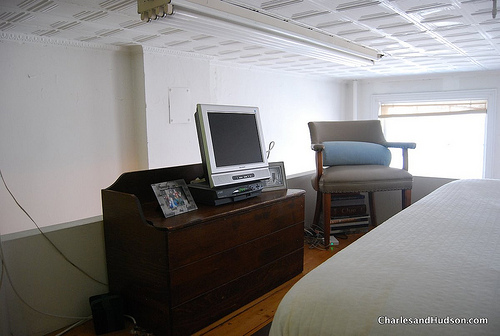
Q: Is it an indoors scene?
A: Yes, it is indoors.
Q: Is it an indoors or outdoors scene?
A: It is indoors.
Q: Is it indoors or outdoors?
A: It is indoors.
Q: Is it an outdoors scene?
A: No, it is indoors.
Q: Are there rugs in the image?
A: No, there are no rugs.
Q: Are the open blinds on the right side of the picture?
A: Yes, the blinds are on the right of the image.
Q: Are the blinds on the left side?
A: No, the blinds are on the right of the image.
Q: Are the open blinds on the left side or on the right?
A: The blinds are on the right of the image.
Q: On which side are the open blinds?
A: The blinds are on the right of the image.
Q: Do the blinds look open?
A: Yes, the blinds are open.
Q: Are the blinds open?
A: Yes, the blinds are open.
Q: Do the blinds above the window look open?
A: Yes, the blinds are open.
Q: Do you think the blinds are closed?
A: No, the blinds are open.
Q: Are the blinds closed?
A: No, the blinds are open.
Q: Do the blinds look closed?
A: No, the blinds are open.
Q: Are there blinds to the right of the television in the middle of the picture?
A: Yes, there are blinds to the right of the television.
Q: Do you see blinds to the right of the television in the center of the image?
A: Yes, there are blinds to the right of the television.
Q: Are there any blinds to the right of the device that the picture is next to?
A: Yes, there are blinds to the right of the television.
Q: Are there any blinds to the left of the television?
A: No, the blinds are to the right of the television.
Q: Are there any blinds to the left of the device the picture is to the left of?
A: No, the blinds are to the right of the television.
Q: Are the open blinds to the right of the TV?
A: Yes, the blinds are to the right of the TV.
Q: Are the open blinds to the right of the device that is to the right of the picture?
A: Yes, the blinds are to the right of the TV.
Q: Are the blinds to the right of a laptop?
A: No, the blinds are to the right of the TV.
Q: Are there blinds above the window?
A: Yes, there are blinds above the window.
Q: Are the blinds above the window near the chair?
A: Yes, the blinds are above the window.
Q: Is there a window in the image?
A: Yes, there is a window.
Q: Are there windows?
A: Yes, there is a window.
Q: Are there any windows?
A: Yes, there is a window.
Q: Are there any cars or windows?
A: Yes, there is a window.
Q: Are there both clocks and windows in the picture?
A: No, there is a window but no clocks.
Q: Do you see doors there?
A: No, there are no doors.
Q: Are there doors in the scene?
A: No, there are no doors.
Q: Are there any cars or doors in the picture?
A: No, there are no doors or cars.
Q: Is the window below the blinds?
A: Yes, the window is below the blinds.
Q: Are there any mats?
A: No, there are no mats.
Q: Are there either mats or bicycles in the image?
A: No, there are no mats or bicycles.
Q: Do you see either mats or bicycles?
A: No, there are no mats or bicycles.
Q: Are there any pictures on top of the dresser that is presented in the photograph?
A: Yes, there is a picture on top of the dresser.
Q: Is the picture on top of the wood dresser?
A: Yes, the picture is on top of the dresser.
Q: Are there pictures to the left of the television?
A: Yes, there is a picture to the left of the television.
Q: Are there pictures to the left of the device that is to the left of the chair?
A: Yes, there is a picture to the left of the television.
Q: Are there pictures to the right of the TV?
A: No, the picture is to the left of the TV.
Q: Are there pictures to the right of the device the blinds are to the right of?
A: No, the picture is to the left of the TV.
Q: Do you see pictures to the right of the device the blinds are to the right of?
A: No, the picture is to the left of the TV.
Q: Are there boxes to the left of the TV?
A: No, there is a picture to the left of the TV.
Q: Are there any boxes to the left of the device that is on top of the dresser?
A: No, there is a picture to the left of the TV.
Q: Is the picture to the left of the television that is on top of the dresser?
A: Yes, the picture is to the left of the TV.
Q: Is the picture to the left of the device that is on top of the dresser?
A: Yes, the picture is to the left of the TV.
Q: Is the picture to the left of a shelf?
A: No, the picture is to the left of the TV.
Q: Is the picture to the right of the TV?
A: No, the picture is to the left of the TV.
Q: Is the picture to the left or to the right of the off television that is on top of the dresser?
A: The picture is to the left of the television.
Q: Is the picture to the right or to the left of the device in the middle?
A: The picture is to the left of the television.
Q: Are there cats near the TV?
A: No, there is a picture near the TV.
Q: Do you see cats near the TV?
A: No, there is a picture near the TV.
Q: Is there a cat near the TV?
A: No, there is a picture near the TV.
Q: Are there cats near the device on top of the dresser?
A: No, there is a picture near the TV.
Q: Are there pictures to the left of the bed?
A: Yes, there is a picture to the left of the bed.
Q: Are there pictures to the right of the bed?
A: No, the picture is to the left of the bed.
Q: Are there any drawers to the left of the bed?
A: No, there is a picture to the left of the bed.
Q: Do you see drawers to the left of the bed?
A: No, there is a picture to the left of the bed.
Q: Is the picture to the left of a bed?
A: Yes, the picture is to the left of a bed.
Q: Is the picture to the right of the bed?
A: No, the picture is to the left of the bed.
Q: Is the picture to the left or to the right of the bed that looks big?
A: The picture is to the left of the bed.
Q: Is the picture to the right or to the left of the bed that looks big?
A: The picture is to the left of the bed.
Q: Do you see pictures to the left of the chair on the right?
A: Yes, there is a picture to the left of the chair.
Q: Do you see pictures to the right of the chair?
A: No, the picture is to the left of the chair.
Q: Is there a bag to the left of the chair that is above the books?
A: No, there is a picture to the left of the chair.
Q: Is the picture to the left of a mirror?
A: No, the picture is to the left of the chair.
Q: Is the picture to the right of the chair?
A: No, the picture is to the left of the chair.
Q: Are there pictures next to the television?
A: Yes, there is a picture next to the television.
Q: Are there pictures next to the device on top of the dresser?
A: Yes, there is a picture next to the television.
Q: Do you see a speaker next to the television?
A: No, there is a picture next to the television.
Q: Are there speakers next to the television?
A: No, there is a picture next to the television.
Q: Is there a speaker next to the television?
A: No, there is a picture next to the television.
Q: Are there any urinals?
A: No, there are no urinals.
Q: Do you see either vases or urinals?
A: No, there are no urinals or vases.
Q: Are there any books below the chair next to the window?
A: Yes, there are books below the chair.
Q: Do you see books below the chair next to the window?
A: Yes, there are books below the chair.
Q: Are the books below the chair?
A: Yes, the books are below the chair.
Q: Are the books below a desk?
A: No, the books are below the chair.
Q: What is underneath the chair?
A: The books are underneath the chair.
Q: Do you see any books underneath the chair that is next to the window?
A: Yes, there are books underneath the chair.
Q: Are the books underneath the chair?
A: Yes, the books are underneath the chair.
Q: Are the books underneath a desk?
A: No, the books are underneath the chair.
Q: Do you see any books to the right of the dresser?
A: Yes, there are books to the right of the dresser.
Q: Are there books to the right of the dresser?
A: Yes, there are books to the right of the dresser.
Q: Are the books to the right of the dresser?
A: Yes, the books are to the right of the dresser.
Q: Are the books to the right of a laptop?
A: No, the books are to the right of the dresser.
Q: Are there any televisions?
A: Yes, there is a television.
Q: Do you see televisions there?
A: Yes, there is a television.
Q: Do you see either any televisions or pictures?
A: Yes, there is a television.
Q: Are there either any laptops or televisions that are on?
A: Yes, the television is on.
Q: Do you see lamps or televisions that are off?
A: Yes, the television is off.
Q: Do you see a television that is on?
A: Yes, there is a television that is on.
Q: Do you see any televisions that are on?
A: Yes, there is a television that is on.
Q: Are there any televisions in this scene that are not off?
A: Yes, there is a television that is on.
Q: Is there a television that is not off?
A: Yes, there is a television that is on.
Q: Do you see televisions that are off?
A: Yes, there is a television that is off.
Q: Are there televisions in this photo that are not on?
A: Yes, there is a television that is off.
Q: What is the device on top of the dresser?
A: The device is a television.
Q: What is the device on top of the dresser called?
A: The device is a television.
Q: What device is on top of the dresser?
A: The device is a television.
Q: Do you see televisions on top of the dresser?
A: Yes, there is a television on top of the dresser.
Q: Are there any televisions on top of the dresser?
A: Yes, there is a television on top of the dresser.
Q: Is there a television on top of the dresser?
A: Yes, there is a television on top of the dresser.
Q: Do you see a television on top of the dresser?
A: Yes, there is a television on top of the dresser.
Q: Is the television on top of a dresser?
A: Yes, the television is on top of a dresser.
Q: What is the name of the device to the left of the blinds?
A: The device is a television.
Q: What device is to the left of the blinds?
A: The device is a television.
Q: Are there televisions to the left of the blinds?
A: Yes, there is a television to the left of the blinds.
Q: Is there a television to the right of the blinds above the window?
A: No, the television is to the left of the blinds.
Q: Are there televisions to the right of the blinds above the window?
A: No, the television is to the left of the blinds.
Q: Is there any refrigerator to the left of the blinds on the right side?
A: No, there is a television to the left of the blinds.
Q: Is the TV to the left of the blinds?
A: Yes, the TV is to the left of the blinds.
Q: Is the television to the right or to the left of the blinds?
A: The television is to the left of the blinds.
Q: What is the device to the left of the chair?
A: The device is a television.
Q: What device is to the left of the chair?
A: The device is a television.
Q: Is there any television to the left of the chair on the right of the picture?
A: Yes, there is a television to the left of the chair.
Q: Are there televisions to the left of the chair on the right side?
A: Yes, there is a television to the left of the chair.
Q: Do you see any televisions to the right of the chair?
A: No, the television is to the left of the chair.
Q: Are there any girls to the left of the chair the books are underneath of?
A: No, there is a television to the left of the chair.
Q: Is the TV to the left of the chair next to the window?
A: Yes, the TV is to the left of the chair.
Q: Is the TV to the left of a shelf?
A: No, the TV is to the left of the chair.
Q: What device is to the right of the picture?
A: The device is a television.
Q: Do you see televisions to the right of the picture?
A: Yes, there is a television to the right of the picture.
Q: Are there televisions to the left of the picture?
A: No, the television is to the right of the picture.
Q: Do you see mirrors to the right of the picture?
A: No, there is a television to the right of the picture.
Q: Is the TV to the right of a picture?
A: Yes, the TV is to the right of a picture.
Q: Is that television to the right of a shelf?
A: No, the television is to the right of a picture.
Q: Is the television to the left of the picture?
A: No, the television is to the right of the picture.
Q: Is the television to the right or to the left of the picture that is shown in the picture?
A: The television is to the right of the picture.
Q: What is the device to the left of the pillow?
A: The device is a television.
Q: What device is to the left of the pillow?
A: The device is a television.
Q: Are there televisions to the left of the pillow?
A: Yes, there is a television to the left of the pillow.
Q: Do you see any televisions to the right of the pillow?
A: No, the television is to the left of the pillow.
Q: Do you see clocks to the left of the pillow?
A: No, there is a television to the left of the pillow.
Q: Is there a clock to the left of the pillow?
A: No, there is a television to the left of the pillow.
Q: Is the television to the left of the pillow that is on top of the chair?
A: Yes, the television is to the left of the pillow.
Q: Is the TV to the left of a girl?
A: No, the TV is to the left of the pillow.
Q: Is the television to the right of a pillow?
A: No, the television is to the left of a pillow.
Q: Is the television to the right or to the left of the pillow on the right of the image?
A: The television is to the left of the pillow.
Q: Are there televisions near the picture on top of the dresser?
A: Yes, there is a television near the picture.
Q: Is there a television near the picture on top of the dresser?
A: Yes, there is a television near the picture.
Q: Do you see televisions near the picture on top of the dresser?
A: Yes, there is a television near the picture.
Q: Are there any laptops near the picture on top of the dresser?
A: No, there is a television near the picture.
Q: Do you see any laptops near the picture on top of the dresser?
A: No, there is a television near the picture.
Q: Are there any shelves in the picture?
A: No, there are no shelves.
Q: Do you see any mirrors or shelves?
A: No, there are no shelves or mirrors.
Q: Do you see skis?
A: No, there are no skis.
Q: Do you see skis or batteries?
A: No, there are no skis or batteries.